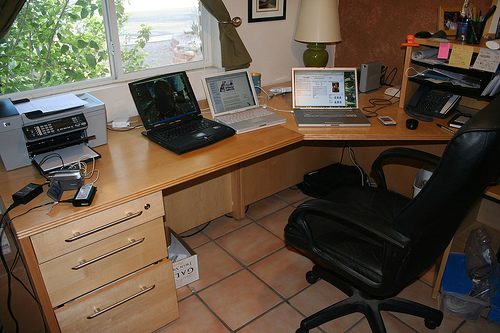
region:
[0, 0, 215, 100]
office window with a metal frame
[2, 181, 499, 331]
brown tile flooring with black grout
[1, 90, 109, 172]
silver printer and scanner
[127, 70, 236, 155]
black open laptop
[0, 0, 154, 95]
large green leafed bush outside the window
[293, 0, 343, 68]
table top lamp with a green base and white shade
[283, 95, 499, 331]
black leather office chair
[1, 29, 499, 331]
light colored wooden desk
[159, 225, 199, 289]
cardboard box with trash in it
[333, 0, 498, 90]
dark brown sponge painted accent wall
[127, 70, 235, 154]
open black laptop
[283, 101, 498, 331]
black leather office chair with arms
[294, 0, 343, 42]
white fabric lamp shade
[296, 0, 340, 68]
green and white table lamp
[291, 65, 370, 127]
open and running silver laptop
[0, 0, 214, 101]
glass window with white trim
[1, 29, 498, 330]
large light brown office desk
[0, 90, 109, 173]
light gray colored printer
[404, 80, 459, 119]
black office phone on desk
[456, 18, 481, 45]
dark blue pencil and pen holder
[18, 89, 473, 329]
A long wood computer desk.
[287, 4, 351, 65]
A small lamp with white shade.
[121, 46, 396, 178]
Three computers on a desk.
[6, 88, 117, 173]
A fax and copier machine.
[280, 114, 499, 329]
A black leather chair.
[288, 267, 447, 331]
Wheel base for the chair.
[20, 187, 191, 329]
Three drawers on the desk.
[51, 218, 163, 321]
Silver handles on the drawers.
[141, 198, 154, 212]
A round lock for the drawers.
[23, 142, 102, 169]
Paper in the paper tray of copier.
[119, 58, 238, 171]
laptop on the table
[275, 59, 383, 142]
laptop on the table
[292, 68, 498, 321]
the chair is empty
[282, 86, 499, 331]
Black leather office chair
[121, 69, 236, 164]
Laptop on the desk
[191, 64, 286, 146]
Laptop on the desk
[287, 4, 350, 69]
Lamp in the background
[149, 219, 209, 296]
Box under the desk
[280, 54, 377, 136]
Laptop on the desk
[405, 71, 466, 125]
Phone on the desk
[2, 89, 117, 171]
Printer under the window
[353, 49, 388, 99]
Modem on the desk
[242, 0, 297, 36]
Picture on the wall